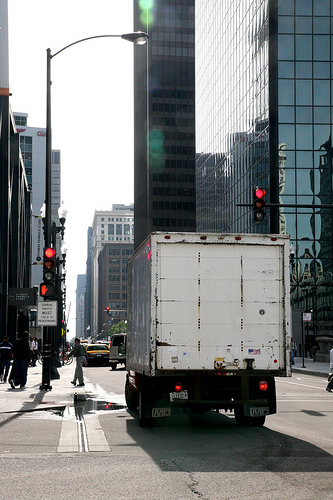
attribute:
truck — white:
[123, 215, 305, 407]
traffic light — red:
[32, 243, 68, 297]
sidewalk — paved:
[26, 371, 45, 422]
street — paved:
[96, 367, 119, 390]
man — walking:
[66, 332, 96, 394]